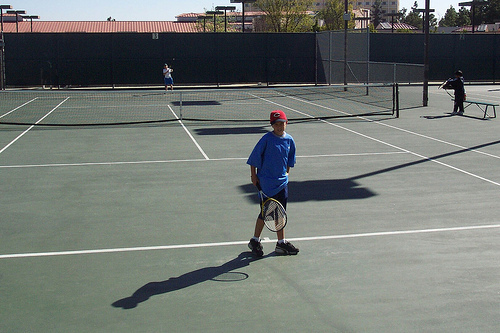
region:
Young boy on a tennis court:
[243, 105, 303, 266]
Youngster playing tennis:
[150, 58, 180, 88]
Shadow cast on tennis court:
[306, 125, 473, 196]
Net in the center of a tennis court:
[38, 83, 219, 123]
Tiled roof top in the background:
[47, 17, 202, 30]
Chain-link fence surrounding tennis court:
[65, 30, 151, 86]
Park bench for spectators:
[445, 92, 497, 119]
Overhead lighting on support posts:
[193, 0, 250, 25]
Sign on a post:
[336, 5, 351, 25]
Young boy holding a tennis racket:
[240, 106, 306, 263]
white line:
[94, 231, 194, 318]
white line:
[87, 234, 177, 288]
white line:
[97, 242, 148, 277]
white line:
[75, 194, 159, 261]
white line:
[20, 198, 115, 288]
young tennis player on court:
[198, 93, 331, 295]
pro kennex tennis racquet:
[246, 194, 281, 237]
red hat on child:
[271, 108, 289, 137]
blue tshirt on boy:
[248, 132, 305, 197]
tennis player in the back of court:
[151, 57, 186, 89]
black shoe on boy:
[268, 236, 304, 257]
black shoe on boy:
[240, 235, 261, 259]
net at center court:
[2, 77, 399, 123]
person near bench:
[433, 62, 473, 122]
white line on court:
[97, 237, 143, 265]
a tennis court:
[53, 66, 485, 291]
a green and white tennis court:
[14, 189, 485, 317]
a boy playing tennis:
[201, 102, 345, 272]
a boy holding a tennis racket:
[196, 60, 323, 262]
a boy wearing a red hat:
[221, 65, 375, 236]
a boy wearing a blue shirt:
[225, 93, 344, 268]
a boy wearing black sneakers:
[223, 108, 313, 284]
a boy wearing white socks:
[234, 107, 324, 271]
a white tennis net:
[11, 65, 431, 142]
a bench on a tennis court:
[431, 55, 495, 125]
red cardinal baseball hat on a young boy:
[268, 109, 288, 121]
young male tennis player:
[243, 109, 300, 256]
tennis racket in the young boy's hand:
[248, 169, 290, 231]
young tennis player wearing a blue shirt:
[246, 109, 300, 256]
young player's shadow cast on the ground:
[103, 248, 255, 314]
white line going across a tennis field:
[2, 219, 498, 262]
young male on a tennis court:
[244, 109, 300, 257]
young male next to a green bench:
[438, 70, 498, 120]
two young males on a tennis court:
[245, 65, 467, 257]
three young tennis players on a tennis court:
[160, 61, 467, 256]